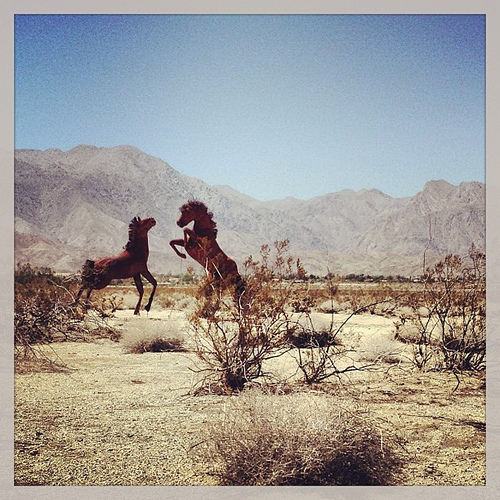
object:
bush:
[182, 382, 398, 484]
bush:
[185, 243, 335, 398]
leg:
[134, 276, 145, 316]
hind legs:
[196, 277, 224, 318]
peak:
[21, 134, 175, 171]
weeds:
[299, 327, 479, 472]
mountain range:
[66, 142, 494, 264]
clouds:
[116, 53, 193, 103]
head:
[128, 215, 157, 232]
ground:
[18, 272, 483, 482]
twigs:
[281, 298, 377, 385]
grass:
[19, 286, 484, 310]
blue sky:
[74, 26, 451, 166]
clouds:
[168, 55, 241, 112]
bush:
[12, 264, 120, 361]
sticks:
[271, 300, 404, 382]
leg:
[170, 238, 187, 258]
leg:
[183, 228, 196, 248]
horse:
[169, 199, 243, 321]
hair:
[122, 216, 137, 250]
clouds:
[376, 97, 439, 142]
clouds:
[208, 134, 294, 172]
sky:
[126, 20, 436, 146]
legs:
[203, 268, 244, 316]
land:
[164, 293, 348, 442]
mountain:
[17, 140, 476, 270]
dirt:
[39, 267, 458, 472]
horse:
[72, 215, 156, 318]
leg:
[85, 284, 93, 307]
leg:
[75, 283, 87, 301]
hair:
[179, 198, 218, 232]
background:
[13, 139, 481, 292]